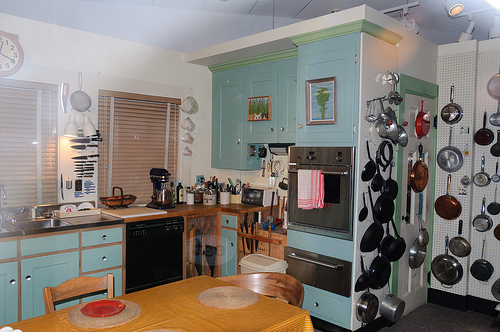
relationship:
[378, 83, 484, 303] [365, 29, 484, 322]
pans hanging wall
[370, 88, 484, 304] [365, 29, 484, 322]
pots hanging wall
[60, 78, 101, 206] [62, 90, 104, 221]
knives on wall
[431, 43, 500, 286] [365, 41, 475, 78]
pans hanging wall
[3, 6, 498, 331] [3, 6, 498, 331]
photo taken kitchen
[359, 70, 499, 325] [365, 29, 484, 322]
pans hanging wall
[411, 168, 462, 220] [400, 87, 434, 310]
two skillets on door.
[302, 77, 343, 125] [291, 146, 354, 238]
tree picture above stove.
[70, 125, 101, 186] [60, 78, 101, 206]
knives on wall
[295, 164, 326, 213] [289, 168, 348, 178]
towels on stove handle.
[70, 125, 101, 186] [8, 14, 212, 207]
knives hanging on wall.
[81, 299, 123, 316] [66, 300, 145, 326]
red plate on wicker placemat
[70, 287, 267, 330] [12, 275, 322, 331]
two woven placemats on table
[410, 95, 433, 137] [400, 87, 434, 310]
red skillet on door.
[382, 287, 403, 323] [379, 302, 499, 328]
soup pot near bottom of floor.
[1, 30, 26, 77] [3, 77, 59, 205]
clock above window.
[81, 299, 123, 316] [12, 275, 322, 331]
red plate on table.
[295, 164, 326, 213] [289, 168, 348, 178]
red and white towel hanging on stove handle.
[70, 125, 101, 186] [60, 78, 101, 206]
knives hanging on middle wall.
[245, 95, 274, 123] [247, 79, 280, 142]
artwork hanging on cabinet door.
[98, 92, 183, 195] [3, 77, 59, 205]
brown mini blinds covering window.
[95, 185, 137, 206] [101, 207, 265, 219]
fruit basket on counter.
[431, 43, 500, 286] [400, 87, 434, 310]
pans beside door.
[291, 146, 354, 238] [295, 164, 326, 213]
oven with towels.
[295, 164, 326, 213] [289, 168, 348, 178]
towels hanging from oven handle.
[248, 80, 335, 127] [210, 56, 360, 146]
pictures on blue cabinets.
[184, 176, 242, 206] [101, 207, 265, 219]
kitchen utensils on counter.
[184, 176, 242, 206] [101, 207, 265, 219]
many utensils on counter.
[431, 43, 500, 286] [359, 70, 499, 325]
pans hanging on wall.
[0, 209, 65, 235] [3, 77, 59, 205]
sink under window.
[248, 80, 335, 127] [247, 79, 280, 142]
pictures on cabinet door.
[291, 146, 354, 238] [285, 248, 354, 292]
steel oven and broiler.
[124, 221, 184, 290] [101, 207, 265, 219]
black dishwasher under counter.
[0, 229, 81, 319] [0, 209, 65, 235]
blue cabinets under sink.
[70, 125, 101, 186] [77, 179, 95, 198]
knives hung by magnets.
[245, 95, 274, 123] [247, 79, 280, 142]
artwork on cabinets.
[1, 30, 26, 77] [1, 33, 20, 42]
clock with beige.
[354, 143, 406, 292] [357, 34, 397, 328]
black frying pans on wall.